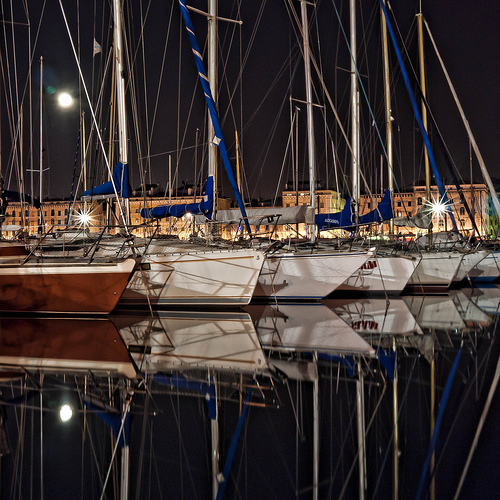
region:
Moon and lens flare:
[43, 73, 76, 113]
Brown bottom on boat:
[0, 274, 137, 316]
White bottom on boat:
[257, 252, 369, 295]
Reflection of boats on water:
[5, 283, 496, 498]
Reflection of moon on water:
[52, 399, 79, 429]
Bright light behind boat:
[417, 191, 454, 219]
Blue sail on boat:
[140, 175, 216, 217]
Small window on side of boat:
[132, 260, 151, 270]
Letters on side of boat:
[360, 259, 382, 269]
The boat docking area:
[0, 0, 497, 499]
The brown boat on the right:
[0, 228, 135, 314]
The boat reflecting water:
[4, 283, 498, 499]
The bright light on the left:
[71, 202, 99, 227]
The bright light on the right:
[425, 191, 452, 223]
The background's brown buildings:
[0, 183, 496, 245]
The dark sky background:
[0, 0, 499, 201]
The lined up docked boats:
[0, 238, 498, 313]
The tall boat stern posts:
[0, 0, 497, 235]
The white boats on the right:
[128, 233, 496, 299]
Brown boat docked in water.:
[21, 255, 99, 313]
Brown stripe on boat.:
[186, 249, 258, 268]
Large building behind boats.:
[24, 195, 124, 223]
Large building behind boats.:
[138, 194, 251, 228]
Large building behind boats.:
[288, 181, 485, 231]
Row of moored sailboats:
[8, 1, 495, 318]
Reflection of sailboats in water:
[0, 280, 497, 498]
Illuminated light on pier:
[56, 91, 87, 232]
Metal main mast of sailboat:
[183, 2, 240, 231]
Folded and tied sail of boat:
[134, 172, 217, 219]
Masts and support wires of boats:
[4, 3, 494, 238]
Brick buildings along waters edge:
[0, 184, 498, 240]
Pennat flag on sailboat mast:
[89, 37, 104, 56]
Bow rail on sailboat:
[18, 221, 160, 266]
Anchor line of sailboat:
[135, 265, 155, 323]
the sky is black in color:
[461, 7, 473, 29]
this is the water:
[241, 412, 388, 459]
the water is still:
[239, 395, 346, 456]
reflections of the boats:
[44, 381, 449, 476]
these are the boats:
[27, 33, 455, 297]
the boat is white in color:
[202, 260, 246, 287]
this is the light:
[52, 88, 76, 138]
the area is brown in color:
[44, 272, 93, 306]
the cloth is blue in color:
[176, 206, 215, 212]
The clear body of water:
[13, 297, 495, 498]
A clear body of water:
[15, 322, 497, 493]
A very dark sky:
[3, 165, 498, 230]